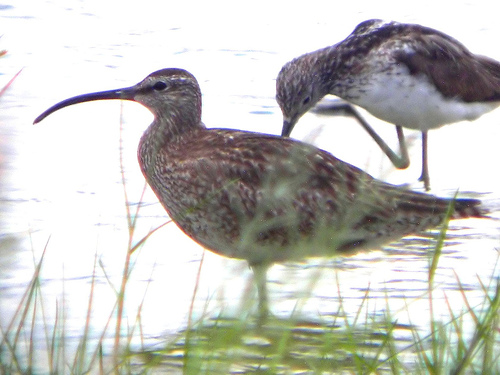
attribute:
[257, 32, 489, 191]
bird — scratching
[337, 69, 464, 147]
belly — white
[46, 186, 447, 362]
grass — green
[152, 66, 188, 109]
eye — black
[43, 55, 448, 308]
birds — brown, white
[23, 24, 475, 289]
birds — standing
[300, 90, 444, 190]
leg — bent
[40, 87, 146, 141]
beak — black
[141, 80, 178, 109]
eye — small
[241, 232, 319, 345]
leg — thin